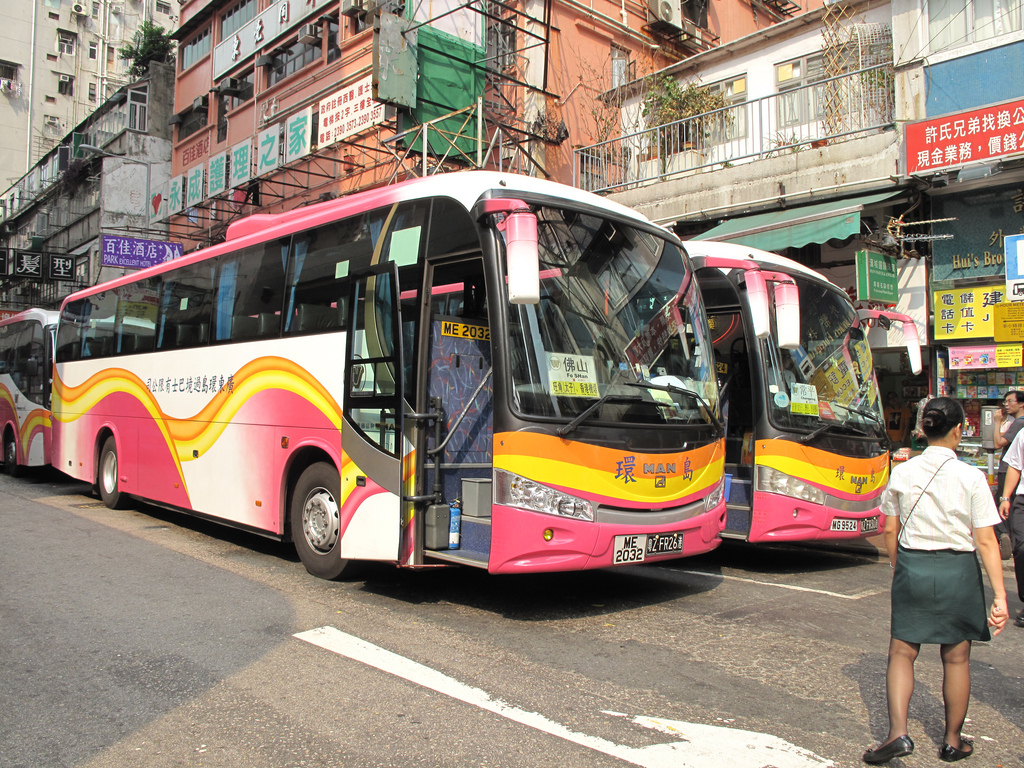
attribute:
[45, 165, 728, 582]
bus — painted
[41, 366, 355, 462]
stripes — yellow